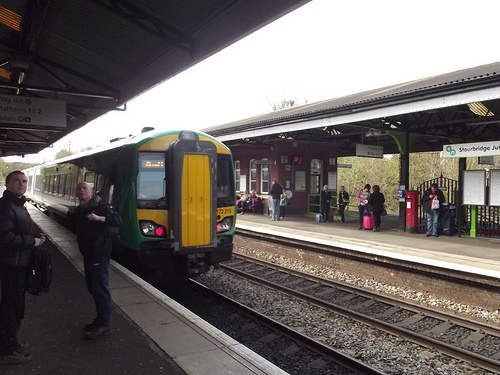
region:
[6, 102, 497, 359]
A train station.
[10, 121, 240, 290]
A train.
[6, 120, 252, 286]
The train is green and yellow.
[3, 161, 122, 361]
Two men looking at something on the ceiling.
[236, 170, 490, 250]
People are on the train platform.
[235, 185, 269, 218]
People sitting on a bench.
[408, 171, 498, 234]
A metal fence behind the platform.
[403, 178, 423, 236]
A red machine on the platform.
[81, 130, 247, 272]
black and yellow train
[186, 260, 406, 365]
tracks on ground for train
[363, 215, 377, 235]
hot pink luggage bag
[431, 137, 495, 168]
white and green sign for train stop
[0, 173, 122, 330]
two men standing by train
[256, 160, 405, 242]
people in train terminal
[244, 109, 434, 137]
roof of train terminal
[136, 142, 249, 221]
front windshield for train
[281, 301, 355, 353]
gravel between the tracks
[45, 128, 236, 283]
a yellow and green train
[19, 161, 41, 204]
a yellow and green train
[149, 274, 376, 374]
a set of train tracks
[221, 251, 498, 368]
a set of train tracks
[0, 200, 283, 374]
a train boarding platform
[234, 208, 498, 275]
a train boarding platform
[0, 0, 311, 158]
an overhead train shelter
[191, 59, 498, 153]
an overhead train shelter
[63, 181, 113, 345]
a man standing on platform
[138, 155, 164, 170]
electronic train destination sign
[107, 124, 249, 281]
A train in the station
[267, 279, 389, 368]
Track ballast on the railway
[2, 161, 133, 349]
Two men standing at the station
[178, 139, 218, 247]
Yellow color on the train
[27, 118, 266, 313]
train on the tracks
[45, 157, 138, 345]
man on the platform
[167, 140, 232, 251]
yellow door on train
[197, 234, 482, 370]
a set of tracks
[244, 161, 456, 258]
a group of people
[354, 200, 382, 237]
a pink suit case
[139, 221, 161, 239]
light on the train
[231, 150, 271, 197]
windows on the building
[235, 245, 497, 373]
gravels on the tracks